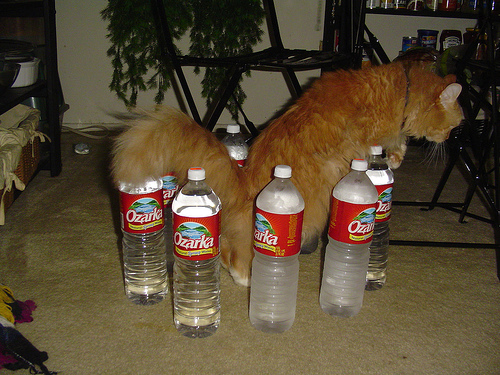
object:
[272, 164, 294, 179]
top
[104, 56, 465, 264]
cat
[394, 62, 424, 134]
neck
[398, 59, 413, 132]
collar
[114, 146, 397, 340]
bottles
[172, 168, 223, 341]
bottle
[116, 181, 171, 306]
bottle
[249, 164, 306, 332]
bottle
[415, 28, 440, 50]
container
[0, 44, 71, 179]
cookware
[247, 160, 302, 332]
water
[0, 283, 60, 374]
clothing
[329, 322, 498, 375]
carpet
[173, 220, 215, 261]
company name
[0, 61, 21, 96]
bowls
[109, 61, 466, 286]
cat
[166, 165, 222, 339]
bottles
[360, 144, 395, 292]
bottle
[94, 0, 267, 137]
plant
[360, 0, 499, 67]
can goods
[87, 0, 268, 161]
plant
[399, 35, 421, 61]
food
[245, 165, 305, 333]
bottle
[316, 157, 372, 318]
bottle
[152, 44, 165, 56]
leaf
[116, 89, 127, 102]
leaf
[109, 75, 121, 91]
leaf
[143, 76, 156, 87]
leaf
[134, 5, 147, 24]
leaf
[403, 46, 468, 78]
breadcrumb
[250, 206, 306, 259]
labels.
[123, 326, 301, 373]
floor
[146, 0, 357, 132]
chair